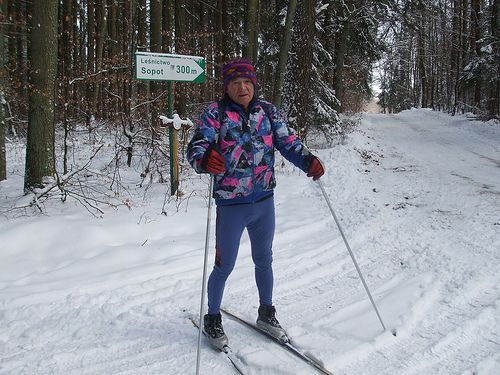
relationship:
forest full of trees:
[3, 2, 496, 199] [7, 5, 138, 194]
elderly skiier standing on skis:
[185, 57, 398, 375] [182, 306, 329, 371]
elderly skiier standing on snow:
[185, 57, 398, 375] [5, 105, 494, 372]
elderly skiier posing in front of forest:
[185, 57, 398, 375] [3, 2, 499, 215]